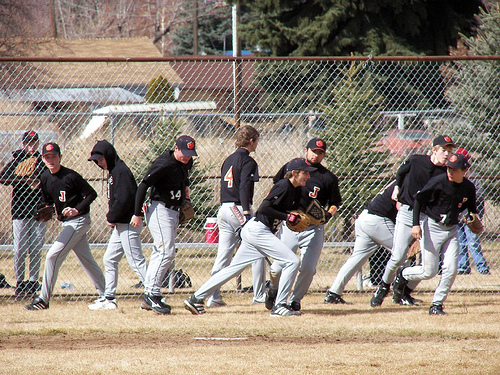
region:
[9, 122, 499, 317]
group of basball players on field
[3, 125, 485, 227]
group of bassball players in black tops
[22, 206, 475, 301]
baseball players all in white pants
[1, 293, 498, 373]
baseball field grass palyers are playing on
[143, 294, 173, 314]
black sneaker of bassball player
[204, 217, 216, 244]
red cooler behind fence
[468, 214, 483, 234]
baseball players glove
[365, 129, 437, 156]
red car in background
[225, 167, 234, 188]
number on back of baseball player shirt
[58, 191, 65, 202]
letter on front of baseball player shirt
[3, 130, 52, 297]
a baseball player with a catcher's mitt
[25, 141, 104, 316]
a baseball player in a black shirt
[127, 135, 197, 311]
a baseball player in a black shirt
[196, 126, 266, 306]
a baseball player in a black shirt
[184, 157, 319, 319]
a baseball player in a black shirt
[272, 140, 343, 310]
a baseball player in a black shirt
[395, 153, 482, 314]
a baseball player in a black shirt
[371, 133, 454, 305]
a baseball player in a black shirt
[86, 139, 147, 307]
a baseball player in a black hoodie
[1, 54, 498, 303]
a tall chain link fence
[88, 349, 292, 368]
brown grass for baseball field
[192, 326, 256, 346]
white plate for the baseball diamond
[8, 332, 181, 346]
brown soil to tell players which path to run on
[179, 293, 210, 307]
black and white sneakers for playing in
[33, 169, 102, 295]
white pants and black sweater for matching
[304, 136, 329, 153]
baseball cap for protection form sun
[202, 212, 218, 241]
cooler with liquid for drinking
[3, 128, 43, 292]
baseball player behind the fence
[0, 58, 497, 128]
fence for keep the field separate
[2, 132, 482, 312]
team of male baseball players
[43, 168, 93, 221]
person wearing a black shirt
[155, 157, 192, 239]
person wearing a black shirt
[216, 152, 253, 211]
person wearing a black shirt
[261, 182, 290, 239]
person wearing a black shirt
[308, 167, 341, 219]
person wearing a black shirt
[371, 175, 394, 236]
person wearing a black shirt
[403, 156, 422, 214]
person wearing a black shirt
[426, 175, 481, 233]
person wearing a black shirt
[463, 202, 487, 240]
person is holding a baseball glove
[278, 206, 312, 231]
person is holding a baseball glove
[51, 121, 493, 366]
men on a baseball field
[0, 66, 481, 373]
men standing on a baseball field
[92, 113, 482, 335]
players on a baseball field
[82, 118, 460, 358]
players on a field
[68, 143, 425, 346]
baseball players on a field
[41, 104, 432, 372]
baseball players on a baseball field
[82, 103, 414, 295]
men in baseball uniforms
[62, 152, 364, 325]
men wearing hats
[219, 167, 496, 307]
men wearing baseball mitts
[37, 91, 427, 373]
men standing outside